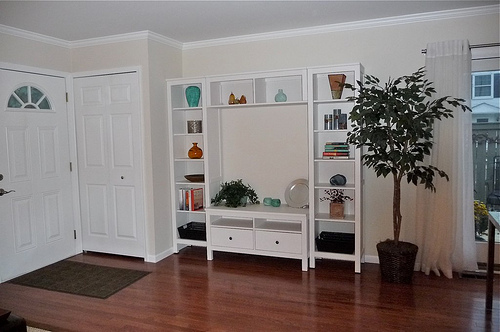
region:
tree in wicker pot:
[348, 64, 425, 299]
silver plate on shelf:
[280, 172, 307, 213]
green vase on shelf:
[181, 83, 201, 107]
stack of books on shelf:
[320, 135, 349, 161]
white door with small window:
[1, 68, 81, 260]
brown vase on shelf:
[323, 72, 346, 97]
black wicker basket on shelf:
[312, 225, 351, 257]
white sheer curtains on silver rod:
[421, 40, 478, 275]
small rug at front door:
[12, 258, 154, 312]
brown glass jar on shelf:
[184, 138, 206, 163]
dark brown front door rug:
[58, 270, 161, 289]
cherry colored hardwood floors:
[169, 268, 290, 330]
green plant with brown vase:
[364, 83, 482, 207]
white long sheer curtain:
[425, 44, 473, 297]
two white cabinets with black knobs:
[205, 215, 313, 266]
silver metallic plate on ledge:
[283, 167, 319, 231]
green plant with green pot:
[221, 165, 259, 209]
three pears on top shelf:
[225, 90, 272, 120]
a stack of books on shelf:
[325, 143, 344, 155]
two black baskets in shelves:
[178, 217, 374, 256]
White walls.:
[2, 1, 493, 276]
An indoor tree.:
[346, 70, 471, 282]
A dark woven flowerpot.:
[376, 237, 416, 283]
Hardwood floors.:
[0, 242, 498, 330]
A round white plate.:
[285, 179, 312, 209]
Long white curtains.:
[414, 41, 476, 279]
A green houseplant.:
[210, 179, 260, 208]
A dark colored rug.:
[17, 255, 153, 305]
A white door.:
[73, 72, 150, 259]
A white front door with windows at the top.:
[0, 69, 85, 283]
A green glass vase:
[183, 85, 203, 107]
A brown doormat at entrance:
[19, 259, 150, 299]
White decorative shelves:
[165, 79, 364, 267]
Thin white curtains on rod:
[416, 42, 481, 277]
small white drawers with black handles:
[208, 221, 313, 272]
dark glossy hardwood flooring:
[3, 246, 492, 323]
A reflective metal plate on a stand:
[274, 175, 314, 211]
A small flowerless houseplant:
[212, 180, 262, 210]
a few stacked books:
[321, 139, 353, 161]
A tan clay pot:
[187, 139, 207, 161]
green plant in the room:
[344, 78, 444, 286]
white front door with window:
[1, 63, 80, 273]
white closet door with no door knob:
[70, 70, 155, 268]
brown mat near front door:
[16, 252, 151, 309]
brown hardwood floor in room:
[2, 239, 499, 330]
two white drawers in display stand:
[205, 221, 311, 259]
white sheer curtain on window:
[414, 38, 464, 287]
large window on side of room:
[467, 64, 499, 271]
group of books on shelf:
[175, 183, 203, 213]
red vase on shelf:
[177, 133, 204, 160]